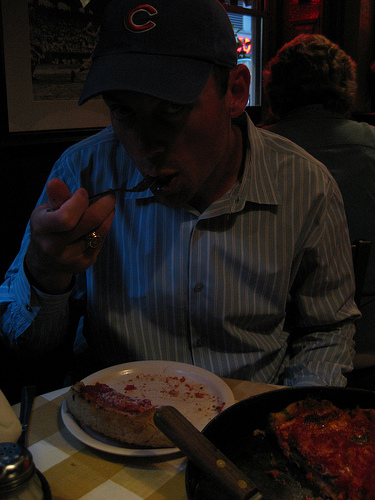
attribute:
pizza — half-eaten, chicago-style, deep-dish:
[63, 335, 216, 491]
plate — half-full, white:
[39, 369, 237, 465]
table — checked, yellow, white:
[10, 385, 190, 493]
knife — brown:
[139, 415, 335, 494]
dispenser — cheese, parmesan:
[10, 439, 40, 498]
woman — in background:
[256, 37, 366, 239]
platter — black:
[192, 333, 375, 499]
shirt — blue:
[5, 104, 342, 381]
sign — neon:
[214, 4, 255, 59]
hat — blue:
[77, 1, 238, 104]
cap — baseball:
[72, 9, 243, 112]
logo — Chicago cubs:
[121, 0, 172, 43]